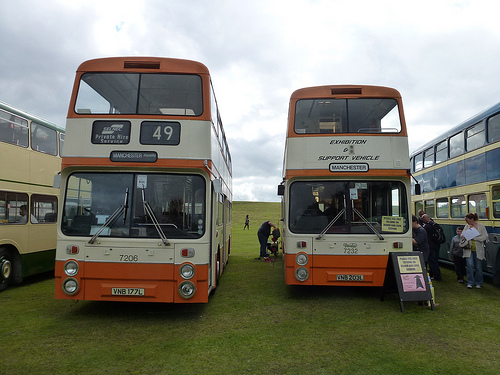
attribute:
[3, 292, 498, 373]
grass — is green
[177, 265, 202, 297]
headlights — shiny 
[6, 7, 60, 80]
clouds — dark 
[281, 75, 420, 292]
bus — orange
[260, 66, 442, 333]
bus — yellow 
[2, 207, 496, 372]
grass — green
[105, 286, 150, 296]
plate — yellow 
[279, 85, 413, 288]
white bus — orange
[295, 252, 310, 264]
headlight — shiny 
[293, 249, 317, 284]
headlights — shiny 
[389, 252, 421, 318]
sign — black